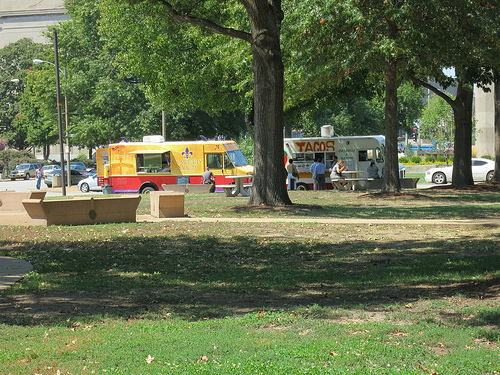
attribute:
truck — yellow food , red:
[95, 131, 257, 189]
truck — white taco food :
[267, 125, 447, 196]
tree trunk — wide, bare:
[204, 14, 325, 238]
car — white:
[413, 151, 498, 217]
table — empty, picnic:
[171, 142, 323, 232]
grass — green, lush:
[158, 261, 265, 324]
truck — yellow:
[72, 111, 267, 197]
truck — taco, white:
[289, 100, 408, 196]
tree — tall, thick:
[229, 67, 302, 212]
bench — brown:
[150, 185, 200, 220]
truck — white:
[282, 121, 397, 208]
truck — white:
[297, 119, 393, 206]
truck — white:
[309, 127, 376, 193]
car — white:
[428, 150, 491, 193]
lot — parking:
[25, 143, 126, 220]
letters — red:
[293, 131, 348, 162]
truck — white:
[275, 115, 421, 213]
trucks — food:
[108, 103, 448, 223]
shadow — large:
[88, 233, 324, 304]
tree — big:
[109, 74, 311, 296]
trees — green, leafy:
[1, 1, 429, 148]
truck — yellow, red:
[94, 134, 254, 191]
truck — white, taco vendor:
[285, 124, 386, 189]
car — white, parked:
[425, 156, 494, 184]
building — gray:
[1, 0, 71, 50]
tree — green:
[95, 3, 382, 137]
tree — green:
[63, 1, 385, 137]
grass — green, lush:
[5, 229, 478, 370]